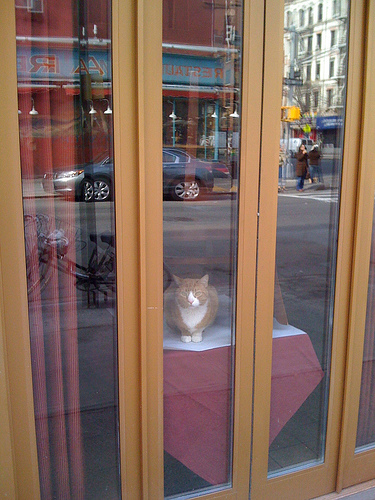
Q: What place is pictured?
A: It is a street.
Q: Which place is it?
A: It is a street.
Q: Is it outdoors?
A: Yes, it is outdoors.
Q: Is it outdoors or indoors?
A: It is outdoors.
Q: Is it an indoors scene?
A: No, it is outdoors.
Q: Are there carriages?
A: No, there are no carriages.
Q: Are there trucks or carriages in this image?
A: No, there are no carriages or trucks.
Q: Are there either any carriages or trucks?
A: No, there are no carriages or trucks.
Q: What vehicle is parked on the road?
A: The vehicle is a car.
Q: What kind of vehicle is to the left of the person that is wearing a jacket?
A: The vehicle is a car.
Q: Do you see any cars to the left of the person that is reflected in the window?
A: Yes, there is a car to the left of the person.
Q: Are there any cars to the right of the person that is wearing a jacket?
A: No, the car is to the left of the person.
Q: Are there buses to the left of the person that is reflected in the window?
A: No, there is a car to the left of the person.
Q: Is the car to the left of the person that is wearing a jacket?
A: Yes, the car is to the left of the person.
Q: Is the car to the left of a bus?
A: No, the car is to the left of the person.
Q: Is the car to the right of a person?
A: No, the car is to the left of a person.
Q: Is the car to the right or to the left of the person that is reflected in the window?
A: The car is to the left of the person.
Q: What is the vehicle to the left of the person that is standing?
A: The vehicle is a car.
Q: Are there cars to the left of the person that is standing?
A: Yes, there is a car to the left of the person.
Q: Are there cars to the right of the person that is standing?
A: No, the car is to the left of the person.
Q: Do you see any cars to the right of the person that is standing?
A: No, the car is to the left of the person.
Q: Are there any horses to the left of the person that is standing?
A: No, there is a car to the left of the person.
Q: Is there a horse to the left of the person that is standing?
A: No, there is a car to the left of the person.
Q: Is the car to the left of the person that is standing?
A: Yes, the car is to the left of the person.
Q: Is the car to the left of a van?
A: No, the car is to the left of the person.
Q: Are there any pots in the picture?
A: No, there are no pots.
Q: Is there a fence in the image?
A: No, there are no fences.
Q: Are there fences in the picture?
A: No, there are no fences.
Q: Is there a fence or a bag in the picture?
A: No, there are no fences or bags.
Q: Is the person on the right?
A: Yes, the person is on the right of the image.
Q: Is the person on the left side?
A: No, the person is on the right of the image.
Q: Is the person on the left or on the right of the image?
A: The person is on the right of the image.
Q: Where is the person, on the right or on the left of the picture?
A: The person is on the right of the image.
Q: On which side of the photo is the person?
A: The person is on the right of the image.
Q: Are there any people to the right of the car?
A: Yes, there is a person to the right of the car.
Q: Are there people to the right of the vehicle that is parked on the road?
A: Yes, there is a person to the right of the car.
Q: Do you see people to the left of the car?
A: No, the person is to the right of the car.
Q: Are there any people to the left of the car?
A: No, the person is to the right of the car.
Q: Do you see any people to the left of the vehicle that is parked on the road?
A: No, the person is to the right of the car.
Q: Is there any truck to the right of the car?
A: No, there is a person to the right of the car.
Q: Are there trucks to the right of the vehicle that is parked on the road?
A: No, there is a person to the right of the car.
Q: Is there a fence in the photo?
A: No, there are no fences.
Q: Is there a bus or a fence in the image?
A: No, there are no fences or buses.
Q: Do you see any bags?
A: No, there are no bags.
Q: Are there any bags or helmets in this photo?
A: No, there are no bags or helmets.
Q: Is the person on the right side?
A: Yes, the person is on the right of the image.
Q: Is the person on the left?
A: No, the person is on the right of the image.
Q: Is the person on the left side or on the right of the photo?
A: The person is on the right of the image.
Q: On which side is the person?
A: The person is on the right of the image.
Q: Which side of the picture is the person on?
A: The person is on the right of the image.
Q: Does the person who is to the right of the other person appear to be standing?
A: Yes, the person is standing.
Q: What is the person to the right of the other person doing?
A: The person is standing.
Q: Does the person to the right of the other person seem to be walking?
A: No, the person is standing.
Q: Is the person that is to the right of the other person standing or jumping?
A: The person is standing.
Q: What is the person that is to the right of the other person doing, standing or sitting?
A: The person is standing.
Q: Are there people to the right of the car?
A: Yes, there is a person to the right of the car.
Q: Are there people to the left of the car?
A: No, the person is to the right of the car.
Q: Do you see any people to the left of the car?
A: No, the person is to the right of the car.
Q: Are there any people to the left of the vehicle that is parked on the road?
A: No, the person is to the right of the car.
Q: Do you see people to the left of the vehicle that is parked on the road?
A: No, the person is to the right of the car.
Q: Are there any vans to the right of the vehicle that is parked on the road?
A: No, there is a person to the right of the car.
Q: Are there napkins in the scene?
A: No, there are no napkins.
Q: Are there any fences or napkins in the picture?
A: No, there are no napkins or fences.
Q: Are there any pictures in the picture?
A: No, there are no pictures.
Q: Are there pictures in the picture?
A: No, there are no pictures.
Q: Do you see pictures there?
A: No, there are no pictures.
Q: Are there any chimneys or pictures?
A: No, there are no pictures or chimneys.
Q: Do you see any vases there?
A: No, there are no vases.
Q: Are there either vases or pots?
A: No, there are no vases or pots.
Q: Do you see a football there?
A: No, there are no footballs.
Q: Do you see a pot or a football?
A: No, there are no footballs or pots.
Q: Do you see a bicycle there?
A: Yes, there is a bicycle.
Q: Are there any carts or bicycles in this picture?
A: Yes, there is a bicycle.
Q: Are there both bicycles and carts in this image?
A: No, there is a bicycle but no carts.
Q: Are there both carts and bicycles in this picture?
A: No, there is a bicycle but no carts.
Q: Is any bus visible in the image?
A: No, there are no buses.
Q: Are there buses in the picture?
A: No, there are no buses.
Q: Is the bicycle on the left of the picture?
A: Yes, the bicycle is on the left of the image.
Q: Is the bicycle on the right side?
A: No, the bicycle is on the left of the image.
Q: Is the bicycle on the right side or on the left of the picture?
A: The bicycle is on the left of the image.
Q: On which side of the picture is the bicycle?
A: The bicycle is on the left of the image.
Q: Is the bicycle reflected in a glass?
A: Yes, the bicycle is reflected in a glass.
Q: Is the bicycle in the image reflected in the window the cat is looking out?
A: Yes, the bicycle is reflected in the window.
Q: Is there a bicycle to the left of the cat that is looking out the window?
A: Yes, there is a bicycle to the left of the cat.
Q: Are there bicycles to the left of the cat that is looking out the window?
A: Yes, there is a bicycle to the left of the cat.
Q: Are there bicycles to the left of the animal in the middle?
A: Yes, there is a bicycle to the left of the cat.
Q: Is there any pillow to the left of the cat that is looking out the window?
A: No, there is a bicycle to the left of the cat.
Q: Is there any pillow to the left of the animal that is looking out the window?
A: No, there is a bicycle to the left of the cat.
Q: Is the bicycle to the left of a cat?
A: Yes, the bicycle is to the left of a cat.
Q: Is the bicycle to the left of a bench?
A: No, the bicycle is to the left of a cat.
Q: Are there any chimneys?
A: No, there are no chimneys.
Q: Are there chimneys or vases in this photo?
A: No, there are no chimneys or vases.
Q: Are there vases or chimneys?
A: No, there are no chimneys or vases.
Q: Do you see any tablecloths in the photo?
A: Yes, there is a tablecloth.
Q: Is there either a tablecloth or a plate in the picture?
A: Yes, there is a tablecloth.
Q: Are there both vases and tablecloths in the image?
A: No, there is a tablecloth but no vases.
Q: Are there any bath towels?
A: No, there are no bath towels.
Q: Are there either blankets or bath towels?
A: No, there are no bath towels or blankets.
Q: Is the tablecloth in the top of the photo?
A: No, the tablecloth is in the bottom of the image.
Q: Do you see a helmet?
A: No, there are no helmets.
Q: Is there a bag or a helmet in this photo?
A: No, there are no helmets or bags.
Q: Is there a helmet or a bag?
A: No, there are no helmets or bags.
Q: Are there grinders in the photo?
A: No, there are no grinders.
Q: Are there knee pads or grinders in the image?
A: No, there are no grinders or knee pads.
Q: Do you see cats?
A: Yes, there is a cat.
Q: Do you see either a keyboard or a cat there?
A: Yes, there is a cat.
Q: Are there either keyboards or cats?
A: Yes, there is a cat.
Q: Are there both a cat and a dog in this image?
A: No, there is a cat but no dogs.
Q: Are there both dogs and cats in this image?
A: No, there is a cat but no dogs.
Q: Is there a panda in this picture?
A: No, there are no pandas.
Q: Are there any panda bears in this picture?
A: No, there are no panda bears.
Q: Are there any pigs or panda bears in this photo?
A: No, there are no panda bears or pigs.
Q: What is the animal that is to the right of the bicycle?
A: The animal is a cat.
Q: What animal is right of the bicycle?
A: The animal is a cat.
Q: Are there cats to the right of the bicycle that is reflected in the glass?
A: Yes, there is a cat to the right of the bicycle.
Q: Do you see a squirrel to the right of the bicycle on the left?
A: No, there is a cat to the right of the bicycle.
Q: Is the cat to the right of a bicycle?
A: Yes, the cat is to the right of a bicycle.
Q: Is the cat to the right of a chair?
A: No, the cat is to the right of a bicycle.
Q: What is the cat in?
A: The cat is in the window.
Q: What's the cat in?
A: The cat is in the window.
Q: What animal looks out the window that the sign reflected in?
A: The cat looks out the window.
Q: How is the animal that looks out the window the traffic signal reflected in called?
A: The animal is a cat.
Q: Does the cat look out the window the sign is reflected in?
A: Yes, the cat looks out the window.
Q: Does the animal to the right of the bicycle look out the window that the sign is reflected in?
A: Yes, the cat looks out the window.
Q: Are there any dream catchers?
A: No, there are no dream catchers.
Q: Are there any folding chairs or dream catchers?
A: No, there are no dream catchers or folding chairs.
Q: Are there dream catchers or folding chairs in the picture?
A: No, there are no dream catchers or folding chairs.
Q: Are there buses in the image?
A: No, there are no buses.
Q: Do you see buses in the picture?
A: No, there are no buses.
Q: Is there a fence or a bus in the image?
A: No, there are no buses or fences.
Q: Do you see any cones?
A: No, there are no cones.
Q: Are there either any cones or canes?
A: No, there are no cones or canes.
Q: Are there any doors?
A: Yes, there is a door.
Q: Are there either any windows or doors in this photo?
A: Yes, there is a door.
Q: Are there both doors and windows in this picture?
A: Yes, there are both a door and a window.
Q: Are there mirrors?
A: No, there are no mirrors.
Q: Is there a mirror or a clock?
A: No, there are no mirrors or clocks.